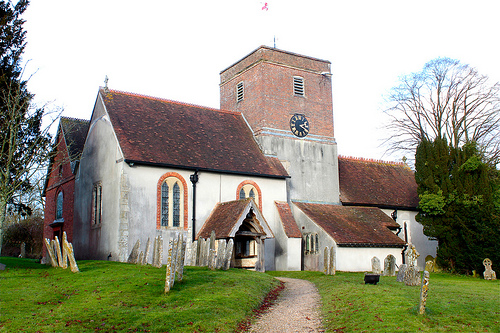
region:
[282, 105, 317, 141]
Large black clock face on the building.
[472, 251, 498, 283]
Old stone tombstone.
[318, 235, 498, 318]
Old cemetery outside a church.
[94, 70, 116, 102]
Cross at the top of the building.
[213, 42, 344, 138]
Portion of the building built with brick.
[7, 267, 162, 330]
Green grass covering the ground.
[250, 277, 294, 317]
Collection of fallen leaves on the ground.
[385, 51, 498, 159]
A large tree with barren leaves.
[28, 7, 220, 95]
bright overcast sky.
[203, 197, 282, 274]
Covered entryway to the church.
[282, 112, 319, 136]
a round black clock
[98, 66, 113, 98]
a grey cross on the roof of the building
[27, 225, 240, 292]
head stones around the building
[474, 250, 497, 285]
a headstone that looks like a ghost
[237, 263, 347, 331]
a path to the church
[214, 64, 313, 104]
two vents on the building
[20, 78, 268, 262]
two parts of the building with pointed roofs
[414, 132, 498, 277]
thick green trees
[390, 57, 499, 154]
leafless trees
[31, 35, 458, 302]
a very large church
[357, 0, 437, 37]
part of the cloudy sky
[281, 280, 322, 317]
part of a footpath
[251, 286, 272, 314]
edge of a footpath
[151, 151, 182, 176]
edge of a roof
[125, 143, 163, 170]
edge of a roof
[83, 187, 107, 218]
part of a window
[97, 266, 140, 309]
part of some grass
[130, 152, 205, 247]
red brick around a window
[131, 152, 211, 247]
red brick around a window on a building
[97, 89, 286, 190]
red brick roof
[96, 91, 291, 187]
red brick on a roof on a building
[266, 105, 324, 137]
a black clock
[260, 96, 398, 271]
a black clock on a building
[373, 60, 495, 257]
tall trees with no leaves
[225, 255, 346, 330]
a tar foot path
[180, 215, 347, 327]
a tar foot path leading up to a door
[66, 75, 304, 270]
cement walls on a building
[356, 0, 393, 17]
part of a cloudy sky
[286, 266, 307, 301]
part of a footpath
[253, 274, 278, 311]
edge of a footpath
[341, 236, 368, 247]
edge of a roof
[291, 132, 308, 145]
part of a clock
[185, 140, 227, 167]
surface of a roof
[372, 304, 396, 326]
part of some grass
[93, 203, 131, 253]
edge of a house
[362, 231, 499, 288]
a group of head stones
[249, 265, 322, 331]
a small gravel path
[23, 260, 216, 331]
leaves on the ground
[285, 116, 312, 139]
clock on the building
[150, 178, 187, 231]
a pair of windows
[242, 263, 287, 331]
leaves on the path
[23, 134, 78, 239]
red brick on building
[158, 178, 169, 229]
window of an old church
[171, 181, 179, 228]
window of an old church